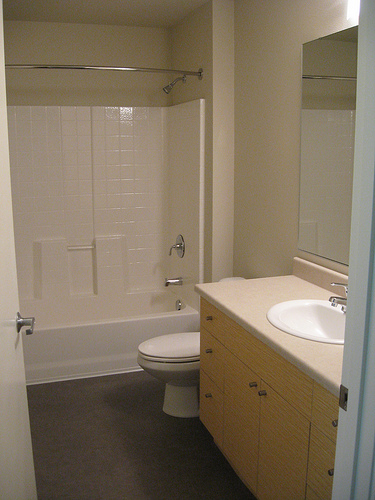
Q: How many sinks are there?
A: One.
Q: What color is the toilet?
A: White.